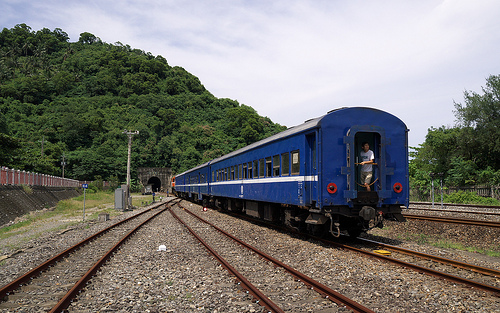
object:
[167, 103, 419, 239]
train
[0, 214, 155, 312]
tracks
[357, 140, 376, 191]
man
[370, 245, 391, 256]
something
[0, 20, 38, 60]
trees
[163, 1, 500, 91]
sky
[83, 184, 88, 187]
sign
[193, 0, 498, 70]
clouds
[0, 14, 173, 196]
hill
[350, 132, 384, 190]
door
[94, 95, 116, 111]
leaves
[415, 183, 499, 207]
fence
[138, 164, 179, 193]
tunnel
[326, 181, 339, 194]
headlight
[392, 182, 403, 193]
headlight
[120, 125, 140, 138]
wire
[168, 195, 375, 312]
tracks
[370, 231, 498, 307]
tracks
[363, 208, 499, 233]
tracks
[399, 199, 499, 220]
tracks